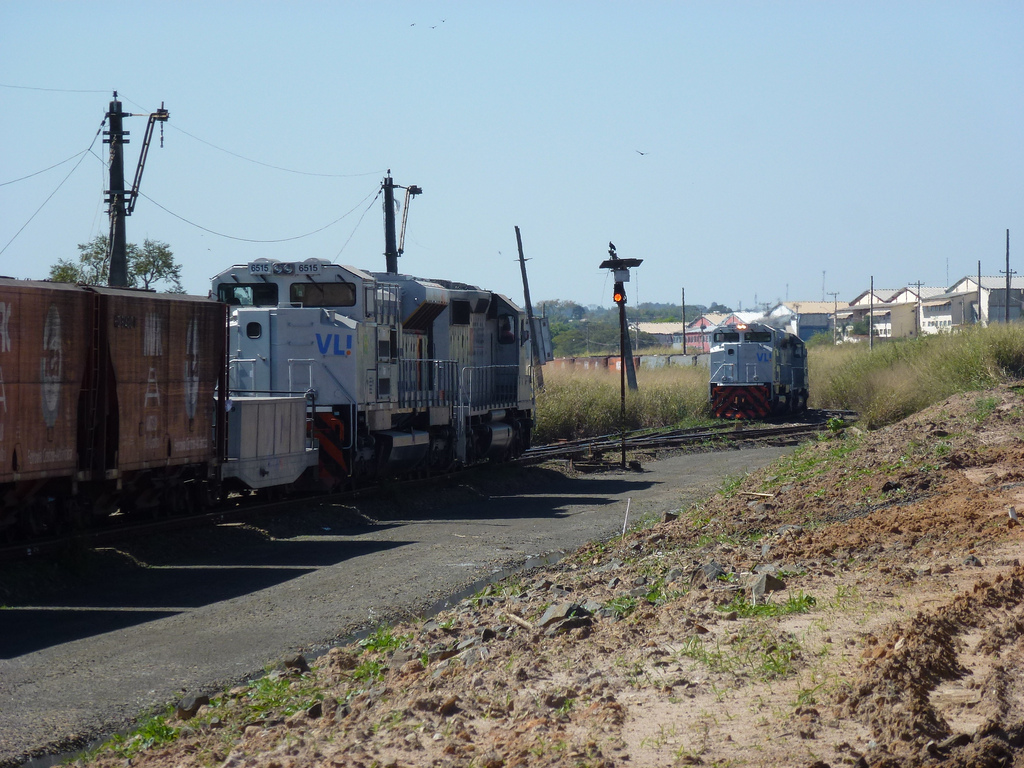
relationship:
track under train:
[0, 407, 846, 566] [0, 258, 542, 540]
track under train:
[0, 406, 859, 768] [0, 258, 542, 540]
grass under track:
[810, 320, 1020, 422] [0, 407, 846, 566]